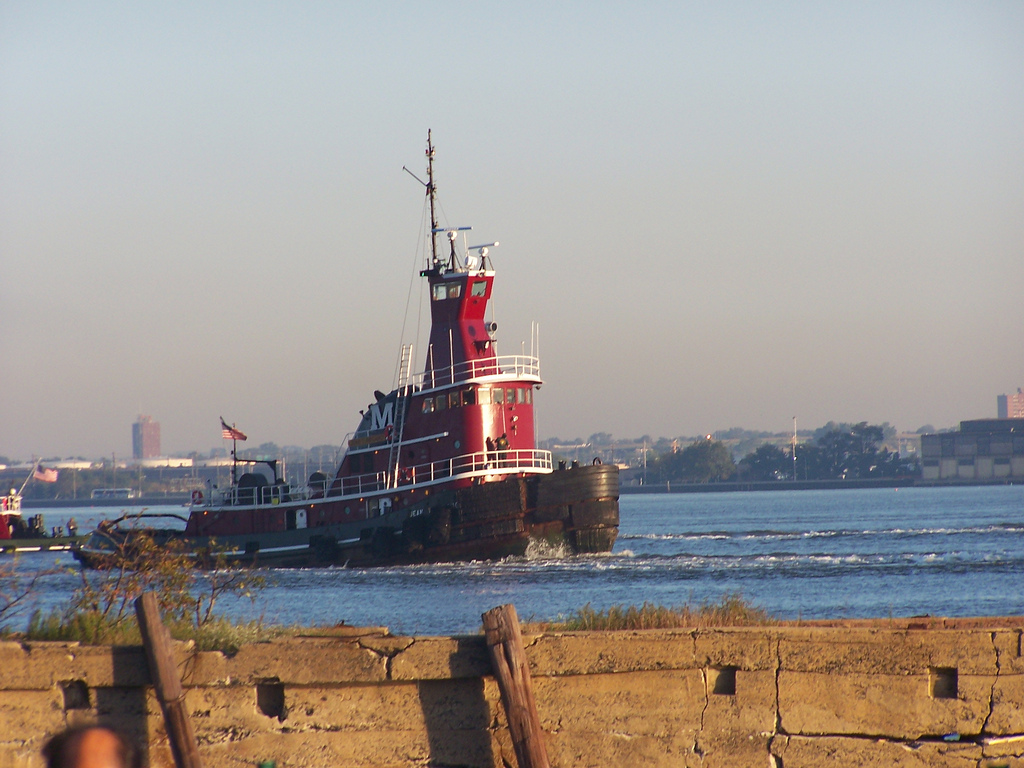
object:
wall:
[2, 619, 1023, 766]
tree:
[43, 509, 271, 643]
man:
[495, 432, 512, 467]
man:
[394, 466, 416, 486]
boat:
[65, 126, 620, 571]